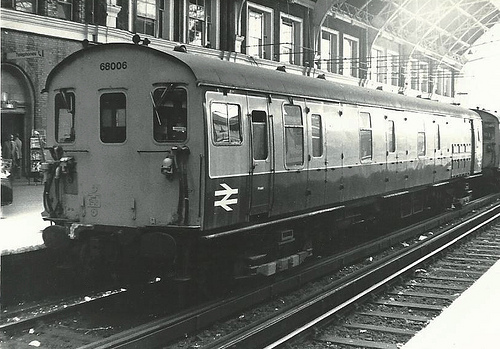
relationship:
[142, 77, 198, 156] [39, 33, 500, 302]
window on rail car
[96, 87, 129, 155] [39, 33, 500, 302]
small window on rail car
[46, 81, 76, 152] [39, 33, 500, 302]
small window on rail car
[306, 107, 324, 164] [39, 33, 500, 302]
small window on rail car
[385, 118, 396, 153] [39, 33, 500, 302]
side window on rail car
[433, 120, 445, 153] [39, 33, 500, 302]
small window on rail car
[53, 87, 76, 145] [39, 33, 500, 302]
small window on rail car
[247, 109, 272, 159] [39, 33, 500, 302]
window on rail car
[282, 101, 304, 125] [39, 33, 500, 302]
window on rail car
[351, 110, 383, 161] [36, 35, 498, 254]
window on train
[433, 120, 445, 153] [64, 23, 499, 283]
small window on train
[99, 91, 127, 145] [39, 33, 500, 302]
window of rail car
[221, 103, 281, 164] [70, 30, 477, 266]
window of train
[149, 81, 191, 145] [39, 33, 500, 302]
window of rail car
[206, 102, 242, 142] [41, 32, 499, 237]
window of train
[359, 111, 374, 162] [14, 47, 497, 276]
window of train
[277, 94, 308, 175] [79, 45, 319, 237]
window of train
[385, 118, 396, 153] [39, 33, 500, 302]
side window of rail car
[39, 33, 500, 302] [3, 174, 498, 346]
rail car on tracks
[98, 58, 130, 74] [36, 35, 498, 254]
number on train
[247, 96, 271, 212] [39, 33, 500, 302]
door on rail car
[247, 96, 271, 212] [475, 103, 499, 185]
door on train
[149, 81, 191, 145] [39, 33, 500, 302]
window on rail car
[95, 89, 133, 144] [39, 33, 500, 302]
window on rail car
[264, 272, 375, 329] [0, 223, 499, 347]
train track on ground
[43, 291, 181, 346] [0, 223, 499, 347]
train track on ground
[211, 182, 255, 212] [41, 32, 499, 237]
symbol on train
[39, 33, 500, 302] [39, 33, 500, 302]
rail car next to rail car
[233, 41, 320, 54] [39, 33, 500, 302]
cable wires from rail car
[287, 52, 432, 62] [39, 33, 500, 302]
cable wires from rail car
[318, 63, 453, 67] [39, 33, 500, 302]
cable wires from rail car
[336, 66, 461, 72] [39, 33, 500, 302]
cable wires from rail car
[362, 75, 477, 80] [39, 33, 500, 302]
cable wires from rail car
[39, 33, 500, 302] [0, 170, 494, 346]
rail car on train tracks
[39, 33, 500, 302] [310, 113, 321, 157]
rail car has window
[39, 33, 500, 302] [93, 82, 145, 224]
rail car has door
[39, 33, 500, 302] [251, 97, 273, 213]
rail car has door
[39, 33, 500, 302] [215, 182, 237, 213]
rail car has symbol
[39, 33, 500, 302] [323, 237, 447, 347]
rail car on tracks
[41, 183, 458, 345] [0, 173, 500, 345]
railroad tracks on ground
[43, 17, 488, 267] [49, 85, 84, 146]
rail car has window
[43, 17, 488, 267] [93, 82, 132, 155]
rail car has window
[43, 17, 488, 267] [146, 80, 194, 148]
rail car has window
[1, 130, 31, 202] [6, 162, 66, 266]
people standing in archway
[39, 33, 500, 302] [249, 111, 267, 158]
rail car has side window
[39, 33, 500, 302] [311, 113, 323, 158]
rail car has small window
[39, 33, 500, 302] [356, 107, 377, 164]
rail car has side window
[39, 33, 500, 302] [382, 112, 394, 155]
rail car has side window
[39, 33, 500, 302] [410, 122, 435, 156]
rail car has side window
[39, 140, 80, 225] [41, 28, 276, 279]
pipes in back of train car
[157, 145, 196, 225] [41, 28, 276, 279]
pipes in back of train car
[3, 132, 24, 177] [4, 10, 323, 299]
people at station